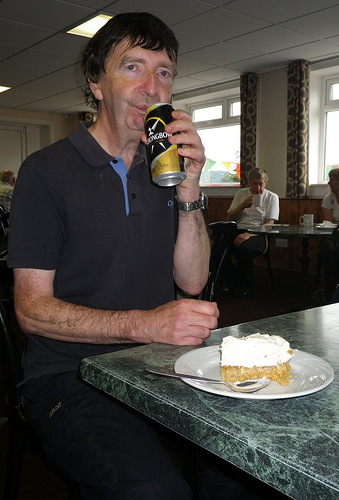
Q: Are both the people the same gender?
A: No, they are both male and female.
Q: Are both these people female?
A: No, they are both male and female.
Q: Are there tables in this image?
A: Yes, there is a table.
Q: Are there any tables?
A: Yes, there is a table.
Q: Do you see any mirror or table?
A: Yes, there is a table.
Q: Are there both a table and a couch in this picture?
A: No, there is a table but no couches.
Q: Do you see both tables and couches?
A: No, there is a table but no couches.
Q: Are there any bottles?
A: No, there are no bottles.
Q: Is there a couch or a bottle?
A: No, there are no bottles or couches.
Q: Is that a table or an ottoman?
A: That is a table.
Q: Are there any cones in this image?
A: No, there are no cones.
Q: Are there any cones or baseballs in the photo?
A: No, there are no cones or baseballs.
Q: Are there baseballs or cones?
A: No, there are no cones or baseballs.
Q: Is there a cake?
A: Yes, there is a cake.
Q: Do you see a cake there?
A: Yes, there is a cake.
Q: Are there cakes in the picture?
A: Yes, there is a cake.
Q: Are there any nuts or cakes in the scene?
A: Yes, there is a cake.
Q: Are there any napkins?
A: No, there are no napkins.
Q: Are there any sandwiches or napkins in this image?
A: No, there are no napkins or sandwiches.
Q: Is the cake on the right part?
A: Yes, the cake is on the right of the image.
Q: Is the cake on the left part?
A: No, the cake is on the right of the image.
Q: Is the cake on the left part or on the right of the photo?
A: The cake is on the right of the image.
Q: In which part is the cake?
A: The cake is on the right of the image.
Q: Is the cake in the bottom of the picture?
A: Yes, the cake is in the bottom of the image.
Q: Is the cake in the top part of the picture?
A: No, the cake is in the bottom of the image.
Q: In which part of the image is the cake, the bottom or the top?
A: The cake is in the bottom of the image.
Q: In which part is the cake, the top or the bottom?
A: The cake is in the bottom of the image.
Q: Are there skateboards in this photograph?
A: No, there are no skateboards.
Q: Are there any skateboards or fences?
A: No, there are no skateboards or fences.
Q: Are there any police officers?
A: No, there are no police officers.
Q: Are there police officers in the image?
A: No, there are no police officers.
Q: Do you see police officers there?
A: No, there are no police officers.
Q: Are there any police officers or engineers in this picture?
A: No, there are no police officers or engineers.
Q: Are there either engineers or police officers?
A: No, there are no police officers or engineers.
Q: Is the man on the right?
A: Yes, the man is on the right of the image.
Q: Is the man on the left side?
A: No, the man is on the right of the image.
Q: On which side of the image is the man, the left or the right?
A: The man is on the right of the image.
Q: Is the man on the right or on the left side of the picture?
A: The man is on the right of the image.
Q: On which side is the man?
A: The man is on the right of the image.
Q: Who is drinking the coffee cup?
A: The man is drinking the coffee cup.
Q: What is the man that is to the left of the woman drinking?
A: The man is drinking coffee cup.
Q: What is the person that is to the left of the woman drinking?
A: The man is drinking coffee cup.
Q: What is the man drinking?
A: The man is drinking coffee cup.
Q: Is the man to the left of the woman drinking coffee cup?
A: Yes, the man is drinking coffee cup.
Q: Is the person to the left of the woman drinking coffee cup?
A: Yes, the man is drinking coffee cup.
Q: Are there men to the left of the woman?
A: Yes, there is a man to the left of the woman.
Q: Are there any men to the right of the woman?
A: No, the man is to the left of the woman.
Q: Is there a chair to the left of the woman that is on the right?
A: No, there is a man to the left of the woman.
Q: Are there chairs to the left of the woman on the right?
A: No, there is a man to the left of the woman.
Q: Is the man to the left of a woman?
A: Yes, the man is to the left of a woman.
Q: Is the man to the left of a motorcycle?
A: No, the man is to the left of a woman.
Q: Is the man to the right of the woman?
A: No, the man is to the left of the woman.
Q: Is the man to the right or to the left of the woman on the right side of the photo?
A: The man is to the left of the woman.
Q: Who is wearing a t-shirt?
A: The man is wearing a t-shirt.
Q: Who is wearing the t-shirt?
A: The man is wearing a t-shirt.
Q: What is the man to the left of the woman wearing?
A: The man is wearing a tee shirt.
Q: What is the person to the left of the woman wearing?
A: The man is wearing a tee shirt.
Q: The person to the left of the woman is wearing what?
A: The man is wearing a tee shirt.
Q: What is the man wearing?
A: The man is wearing a tee shirt.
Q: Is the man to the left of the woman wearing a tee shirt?
A: Yes, the man is wearing a tee shirt.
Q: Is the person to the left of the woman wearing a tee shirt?
A: Yes, the man is wearing a tee shirt.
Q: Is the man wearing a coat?
A: No, the man is wearing a tee shirt.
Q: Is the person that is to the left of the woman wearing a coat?
A: No, the man is wearing a tee shirt.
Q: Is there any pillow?
A: No, there are no pillows.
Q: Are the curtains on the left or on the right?
A: The curtains are on the right of the image.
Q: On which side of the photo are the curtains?
A: The curtains are on the right of the image.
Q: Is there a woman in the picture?
A: Yes, there is a woman.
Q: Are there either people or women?
A: Yes, there is a woman.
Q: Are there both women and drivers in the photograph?
A: No, there is a woman but no drivers.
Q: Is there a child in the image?
A: No, there are no children.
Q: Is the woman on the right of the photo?
A: Yes, the woman is on the right of the image.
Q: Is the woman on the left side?
A: No, the woman is on the right of the image.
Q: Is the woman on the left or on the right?
A: The woman is on the right of the image.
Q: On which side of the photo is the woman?
A: The woman is on the right of the image.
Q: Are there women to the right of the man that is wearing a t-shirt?
A: Yes, there is a woman to the right of the man.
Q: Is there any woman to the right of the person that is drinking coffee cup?
A: Yes, there is a woman to the right of the man.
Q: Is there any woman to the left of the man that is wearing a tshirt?
A: No, the woman is to the right of the man.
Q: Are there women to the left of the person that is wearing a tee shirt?
A: No, the woman is to the right of the man.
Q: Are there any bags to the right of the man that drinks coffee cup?
A: No, there is a woman to the right of the man.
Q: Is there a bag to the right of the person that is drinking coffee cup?
A: No, there is a woman to the right of the man.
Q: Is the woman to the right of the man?
A: Yes, the woman is to the right of the man.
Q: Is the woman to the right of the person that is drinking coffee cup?
A: Yes, the woman is to the right of the man.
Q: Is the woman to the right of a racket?
A: No, the woman is to the right of the man.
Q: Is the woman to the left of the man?
A: No, the woman is to the right of the man.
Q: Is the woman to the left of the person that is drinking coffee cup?
A: No, the woman is to the right of the man.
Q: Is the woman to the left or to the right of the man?
A: The woman is to the right of the man.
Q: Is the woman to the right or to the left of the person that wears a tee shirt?
A: The woman is to the right of the man.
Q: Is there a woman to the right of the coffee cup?
A: Yes, there is a woman to the right of the coffee cup.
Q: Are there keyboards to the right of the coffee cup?
A: No, there is a woman to the right of the coffee cup.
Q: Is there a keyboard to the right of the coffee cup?
A: No, there is a woman to the right of the coffee cup.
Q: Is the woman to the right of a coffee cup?
A: Yes, the woman is to the right of a coffee cup.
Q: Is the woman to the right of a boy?
A: No, the woman is to the right of a coffee cup.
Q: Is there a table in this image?
A: Yes, there is a table.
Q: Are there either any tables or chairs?
A: Yes, there is a table.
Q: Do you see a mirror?
A: No, there are no mirrors.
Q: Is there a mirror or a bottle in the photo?
A: No, there are no mirrors or bottles.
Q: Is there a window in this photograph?
A: Yes, there is a window.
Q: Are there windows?
A: Yes, there is a window.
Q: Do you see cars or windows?
A: Yes, there is a window.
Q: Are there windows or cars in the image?
A: Yes, there is a window.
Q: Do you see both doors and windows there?
A: No, there is a window but no doors.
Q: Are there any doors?
A: No, there are no doors.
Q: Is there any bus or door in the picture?
A: No, there are no doors or buses.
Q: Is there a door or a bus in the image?
A: No, there are no doors or buses.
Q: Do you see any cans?
A: Yes, there is a can.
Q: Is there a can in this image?
A: Yes, there is a can.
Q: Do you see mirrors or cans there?
A: Yes, there is a can.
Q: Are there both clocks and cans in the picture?
A: No, there is a can but no clocks.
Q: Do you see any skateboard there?
A: No, there are no skateboards.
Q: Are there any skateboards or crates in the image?
A: No, there are no skateboards or crates.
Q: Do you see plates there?
A: Yes, there is a plate.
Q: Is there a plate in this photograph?
A: Yes, there is a plate.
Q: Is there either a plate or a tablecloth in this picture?
A: Yes, there is a plate.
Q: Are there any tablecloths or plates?
A: Yes, there is a plate.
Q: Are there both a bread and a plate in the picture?
A: No, there is a plate but no breads.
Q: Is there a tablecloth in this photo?
A: No, there are no tablecloths.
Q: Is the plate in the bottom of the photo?
A: Yes, the plate is in the bottom of the image.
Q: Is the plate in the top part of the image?
A: No, the plate is in the bottom of the image.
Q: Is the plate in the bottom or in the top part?
A: The plate is in the bottom of the image.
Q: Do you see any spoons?
A: Yes, there is a spoon.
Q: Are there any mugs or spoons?
A: Yes, there is a spoon.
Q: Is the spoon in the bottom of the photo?
A: Yes, the spoon is in the bottom of the image.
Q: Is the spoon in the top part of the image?
A: No, the spoon is in the bottom of the image.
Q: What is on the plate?
A: The spoon is on the plate.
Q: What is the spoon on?
A: The spoon is on the plate.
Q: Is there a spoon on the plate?
A: Yes, there is a spoon on the plate.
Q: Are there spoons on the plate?
A: Yes, there is a spoon on the plate.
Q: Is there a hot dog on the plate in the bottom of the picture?
A: No, there is a spoon on the plate.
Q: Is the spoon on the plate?
A: Yes, the spoon is on the plate.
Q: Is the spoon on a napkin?
A: No, the spoon is on the plate.